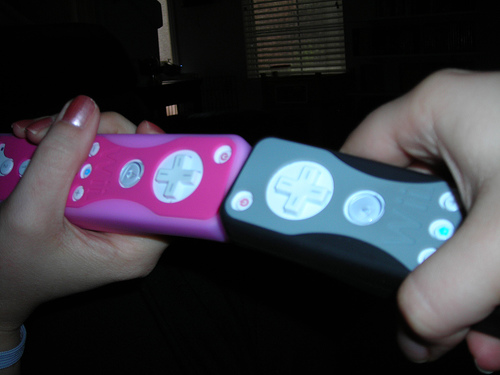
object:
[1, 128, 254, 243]
controller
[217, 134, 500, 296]
controller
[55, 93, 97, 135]
fingernail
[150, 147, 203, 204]
function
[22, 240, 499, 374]
space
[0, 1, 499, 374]
room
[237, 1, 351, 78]
blind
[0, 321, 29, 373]
bracelet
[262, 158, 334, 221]
button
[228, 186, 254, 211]
button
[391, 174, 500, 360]
thumb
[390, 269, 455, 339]
knuckle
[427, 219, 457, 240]
button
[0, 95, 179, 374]
person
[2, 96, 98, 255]
thumb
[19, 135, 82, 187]
knuckle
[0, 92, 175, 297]
hand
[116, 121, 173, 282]
finger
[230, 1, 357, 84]
window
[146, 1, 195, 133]
doorway